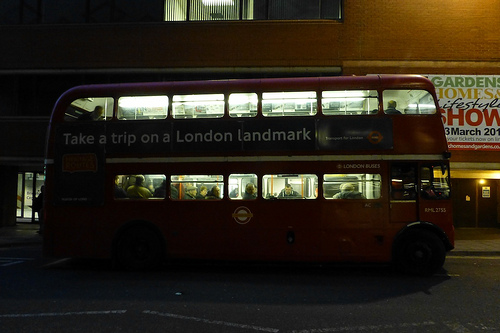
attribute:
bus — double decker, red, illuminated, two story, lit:
[37, 72, 456, 279]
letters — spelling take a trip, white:
[61, 129, 137, 148]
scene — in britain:
[0, 1, 499, 333]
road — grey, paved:
[1, 240, 499, 333]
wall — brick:
[0, 0, 498, 71]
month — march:
[450, 125, 483, 138]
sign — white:
[417, 74, 499, 153]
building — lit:
[0, 1, 499, 226]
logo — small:
[229, 204, 255, 226]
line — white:
[0, 307, 127, 320]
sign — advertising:
[58, 117, 391, 155]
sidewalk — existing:
[443, 226, 499, 256]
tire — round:
[116, 225, 161, 273]